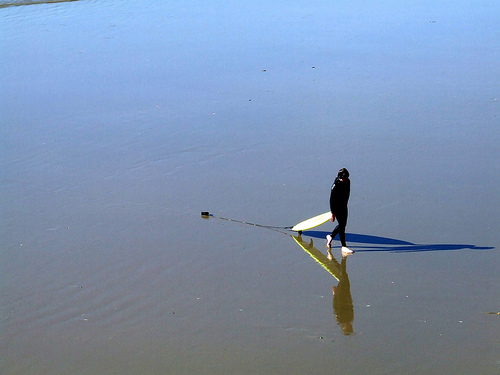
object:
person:
[326, 167, 355, 253]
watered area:
[3, 1, 500, 375]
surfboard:
[290, 210, 334, 232]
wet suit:
[329, 178, 351, 246]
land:
[1, 0, 82, 10]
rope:
[210, 213, 292, 236]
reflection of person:
[328, 243, 495, 255]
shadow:
[296, 226, 413, 246]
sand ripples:
[39, 294, 195, 342]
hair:
[337, 168, 350, 179]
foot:
[326, 234, 333, 248]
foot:
[341, 247, 354, 254]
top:
[322, 210, 335, 217]